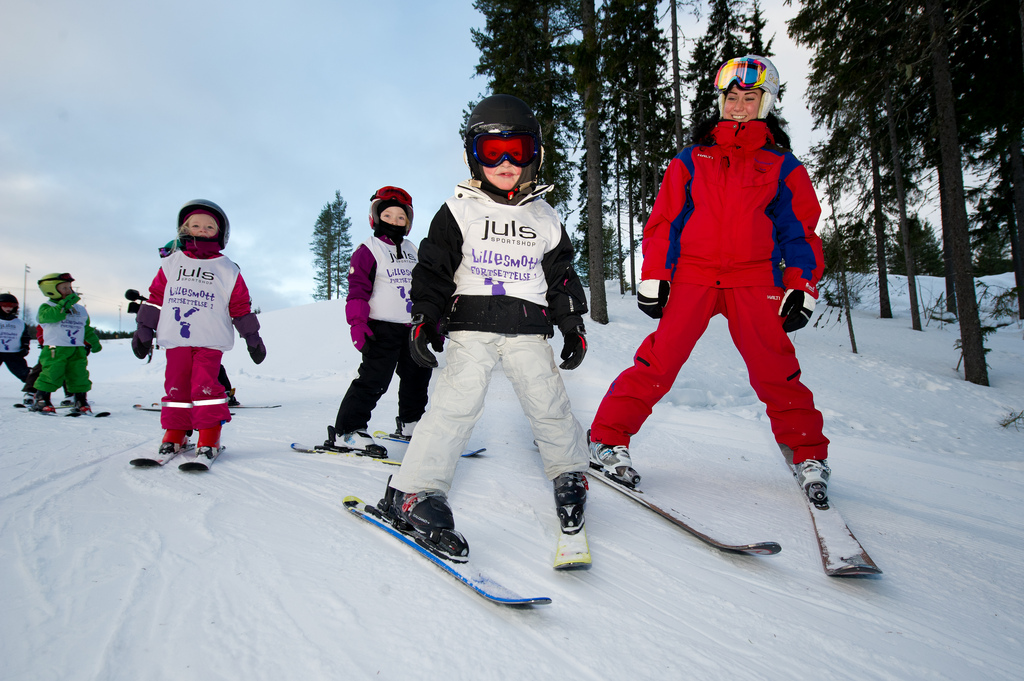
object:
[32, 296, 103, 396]
suit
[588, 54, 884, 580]
instructor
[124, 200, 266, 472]
child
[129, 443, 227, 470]
skis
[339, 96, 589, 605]
children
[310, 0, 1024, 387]
trees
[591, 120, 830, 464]
red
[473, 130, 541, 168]
goggles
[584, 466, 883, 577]
skis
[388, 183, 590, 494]
suit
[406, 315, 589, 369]
gloves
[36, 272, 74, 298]
helmet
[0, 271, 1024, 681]
snow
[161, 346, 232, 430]
pants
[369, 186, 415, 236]
helmets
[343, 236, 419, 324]
jacket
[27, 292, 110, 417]
outfit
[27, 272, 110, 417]
child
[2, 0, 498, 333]
sky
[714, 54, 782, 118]
helmet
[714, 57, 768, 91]
goggles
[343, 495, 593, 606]
skis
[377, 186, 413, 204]
goggles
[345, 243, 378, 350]
arms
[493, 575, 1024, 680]
lines